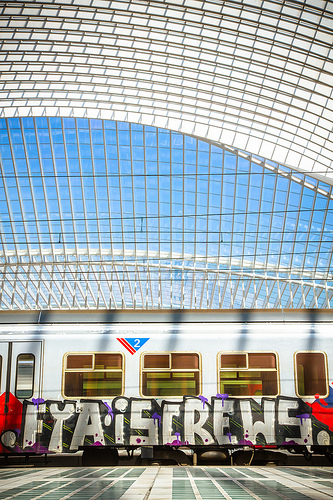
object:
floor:
[1, 464, 331, 497]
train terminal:
[5, 5, 329, 499]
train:
[0, 319, 328, 464]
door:
[7, 339, 42, 448]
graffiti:
[145, 408, 165, 429]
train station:
[1, 250, 330, 497]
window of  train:
[94, 355, 121, 369]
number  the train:
[134, 339, 141, 348]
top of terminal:
[1, 3, 330, 307]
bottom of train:
[4, 447, 330, 465]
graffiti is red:
[323, 412, 331, 424]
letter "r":
[182, 395, 213, 449]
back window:
[294, 352, 329, 398]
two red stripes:
[116, 337, 134, 355]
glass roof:
[4, 2, 328, 312]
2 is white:
[134, 338, 140, 347]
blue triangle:
[124, 337, 150, 351]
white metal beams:
[46, 116, 58, 175]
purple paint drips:
[2, 393, 55, 457]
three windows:
[63, 351, 125, 398]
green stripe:
[4, 482, 27, 499]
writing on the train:
[20, 396, 318, 449]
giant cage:
[2, 7, 331, 499]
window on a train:
[219, 355, 248, 369]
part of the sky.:
[219, 180, 328, 303]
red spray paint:
[1, 418, 16, 430]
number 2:
[134, 339, 140, 348]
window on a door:
[17, 355, 32, 396]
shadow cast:
[167, 309, 182, 351]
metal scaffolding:
[10, 5, 329, 256]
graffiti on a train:
[2, 389, 331, 464]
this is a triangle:
[116, 337, 150, 356]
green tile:
[172, 490, 193, 497]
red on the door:
[6, 404, 19, 427]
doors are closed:
[8, 335, 42, 448]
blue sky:
[3, 116, 126, 248]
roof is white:
[1, 3, 332, 126]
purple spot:
[304, 439, 308, 443]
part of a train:
[58, 339, 85, 454]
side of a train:
[180, 306, 328, 457]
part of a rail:
[4, 454, 39, 464]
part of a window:
[62, 371, 99, 397]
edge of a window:
[121, 352, 127, 400]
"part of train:
[108, 320, 134, 372]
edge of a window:
[275, 353, 282, 398]